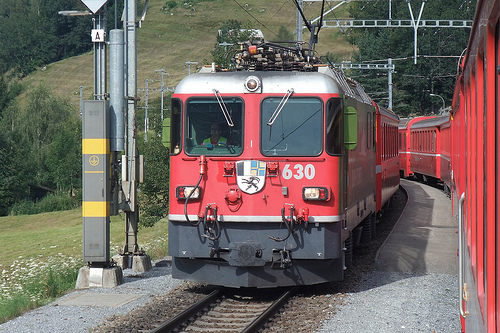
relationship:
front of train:
[169, 77, 348, 283] [172, 71, 410, 292]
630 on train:
[282, 160, 317, 186] [172, 71, 410, 292]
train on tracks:
[172, 71, 410, 292] [145, 287, 322, 333]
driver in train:
[202, 123, 229, 151] [172, 71, 410, 292]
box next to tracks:
[81, 102, 109, 263] [145, 287, 322, 333]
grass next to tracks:
[4, 202, 169, 313] [145, 287, 322, 333]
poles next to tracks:
[84, 2, 153, 275] [145, 287, 322, 333]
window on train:
[184, 98, 240, 156] [172, 71, 410, 292]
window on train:
[261, 97, 322, 153] [172, 71, 410, 292]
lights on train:
[178, 189, 327, 203] [172, 71, 410, 292]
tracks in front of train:
[145, 287, 322, 333] [172, 71, 410, 292]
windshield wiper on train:
[211, 89, 232, 125] [172, 71, 410, 292]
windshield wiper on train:
[263, 86, 301, 125] [172, 71, 410, 292]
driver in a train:
[202, 123, 229, 151] [172, 71, 410, 292]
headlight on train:
[181, 187, 199, 199] [172, 71, 410, 292]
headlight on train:
[299, 188, 327, 200] [172, 71, 410, 292]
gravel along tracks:
[36, 269, 467, 333] [145, 287, 322, 333]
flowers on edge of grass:
[4, 230, 163, 300] [4, 202, 169, 313]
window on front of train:
[184, 98, 240, 156] [172, 71, 410, 292]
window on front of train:
[261, 97, 322, 153] [172, 71, 410, 292]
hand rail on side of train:
[458, 190, 477, 326] [172, 71, 410, 292]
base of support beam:
[115, 253, 148, 277] [122, 2, 141, 254]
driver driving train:
[202, 123, 229, 151] [172, 71, 410, 292]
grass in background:
[20, 2, 334, 96] [2, 2, 481, 117]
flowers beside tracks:
[4, 230, 163, 300] [145, 287, 322, 333]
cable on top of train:
[284, 5, 330, 57] [172, 71, 410, 292]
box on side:
[81, 102, 109, 263] [9, 92, 162, 291]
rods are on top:
[293, 7, 470, 84] [275, 2, 470, 119]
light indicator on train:
[241, 76, 263, 93] [172, 71, 410, 292]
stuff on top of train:
[201, 29, 335, 80] [172, 71, 410, 292]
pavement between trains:
[343, 173, 465, 332] [172, 7, 495, 328]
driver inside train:
[202, 123, 229, 151] [172, 71, 410, 292]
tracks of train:
[145, 287, 322, 333] [172, 71, 410, 292]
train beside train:
[172, 71, 410, 292] [405, 0, 500, 331]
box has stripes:
[81, 102, 109, 263] [82, 137, 106, 225]